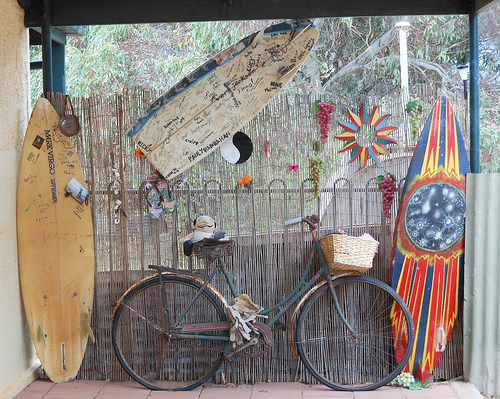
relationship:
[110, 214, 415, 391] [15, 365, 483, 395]
bicycle on ground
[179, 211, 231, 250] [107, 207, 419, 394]
toy on bike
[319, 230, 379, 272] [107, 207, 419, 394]
basket on bike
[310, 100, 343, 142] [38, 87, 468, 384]
grape on wall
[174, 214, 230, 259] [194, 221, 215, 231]
doll with mustache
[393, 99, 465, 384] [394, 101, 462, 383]
board with stripes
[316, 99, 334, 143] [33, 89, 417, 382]
grape hanging on fence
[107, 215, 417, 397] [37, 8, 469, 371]
bicycle parked against wall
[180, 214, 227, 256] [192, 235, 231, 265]
doll on bicycle seat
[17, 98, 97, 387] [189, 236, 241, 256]
tan wood on bicycle seat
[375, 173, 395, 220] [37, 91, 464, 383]
grapes on fence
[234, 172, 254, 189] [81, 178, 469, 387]
orange flower sitting on fence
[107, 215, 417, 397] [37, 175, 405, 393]
bicycle parked at railing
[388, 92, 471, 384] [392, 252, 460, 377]
board with stripes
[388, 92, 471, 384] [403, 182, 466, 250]
board with circle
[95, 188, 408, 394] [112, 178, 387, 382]
railing with pipes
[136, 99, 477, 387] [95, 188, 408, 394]
fence along railing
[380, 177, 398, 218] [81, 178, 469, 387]
grapes on fence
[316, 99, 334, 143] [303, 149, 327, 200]
grape in a bunch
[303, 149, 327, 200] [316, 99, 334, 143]
bunch of grape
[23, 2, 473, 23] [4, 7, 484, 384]
ceiling of balcony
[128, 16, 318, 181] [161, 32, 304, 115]
surfboard covered with signatures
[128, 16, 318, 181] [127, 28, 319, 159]
surfboard with writing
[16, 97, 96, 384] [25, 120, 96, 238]
board with writing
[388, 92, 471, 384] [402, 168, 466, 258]
board with pattern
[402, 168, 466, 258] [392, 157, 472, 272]
pattern in middle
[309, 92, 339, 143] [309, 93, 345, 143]
bunch of grapes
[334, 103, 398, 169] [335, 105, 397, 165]
sun pattern with points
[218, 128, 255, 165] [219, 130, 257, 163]
round disk with ying yang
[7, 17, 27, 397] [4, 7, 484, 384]
wall of balcony